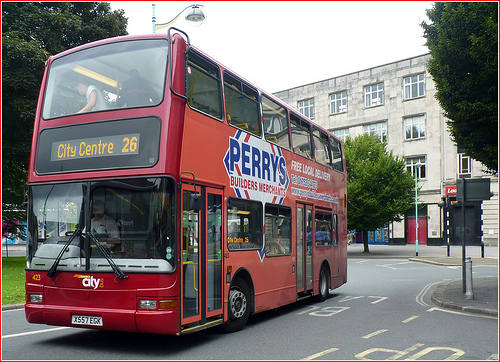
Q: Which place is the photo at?
A: It is at the road.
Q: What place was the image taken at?
A: It was taken at the road.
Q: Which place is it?
A: It is a road.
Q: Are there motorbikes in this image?
A: No, there are no motorbikes.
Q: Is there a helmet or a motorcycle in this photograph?
A: No, there are no motorcycles or helmets.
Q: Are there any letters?
A: Yes, there are letters.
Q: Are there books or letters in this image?
A: Yes, there are letters.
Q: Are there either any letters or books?
A: Yes, there are letters.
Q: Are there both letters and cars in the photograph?
A: No, there are letters but no cars.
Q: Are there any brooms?
A: No, there are no brooms.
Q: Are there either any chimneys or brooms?
A: No, there are no brooms or chimneys.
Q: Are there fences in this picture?
A: No, there are no fences.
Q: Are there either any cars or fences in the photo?
A: No, there are no fences or cars.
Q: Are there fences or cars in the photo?
A: No, there are no fences or cars.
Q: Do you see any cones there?
A: No, there are no cones.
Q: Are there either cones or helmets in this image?
A: No, there are no cones or helmets.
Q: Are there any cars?
A: No, there are no cars.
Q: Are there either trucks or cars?
A: No, there are no cars or trucks.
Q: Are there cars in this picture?
A: No, there are no cars.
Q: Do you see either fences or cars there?
A: No, there are no cars or fences.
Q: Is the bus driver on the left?
A: Yes, the driver is on the left of the image.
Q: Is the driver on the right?
A: No, the driver is on the left of the image.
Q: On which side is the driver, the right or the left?
A: The driver is on the left of the image.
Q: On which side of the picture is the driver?
A: The driver is on the left of the image.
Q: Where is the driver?
A: The driver is on the bus.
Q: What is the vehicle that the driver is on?
A: The vehicle is a bus.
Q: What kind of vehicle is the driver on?
A: The driver is on the bus.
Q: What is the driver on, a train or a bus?
A: The driver is on a bus.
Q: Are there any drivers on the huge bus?
A: Yes, there is a driver on the bus.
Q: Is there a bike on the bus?
A: No, there is a driver on the bus.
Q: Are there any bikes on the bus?
A: No, there is a driver on the bus.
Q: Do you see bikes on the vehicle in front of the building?
A: No, there is a driver on the bus.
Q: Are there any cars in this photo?
A: No, there are no cars.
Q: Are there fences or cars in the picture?
A: No, there are no cars or fences.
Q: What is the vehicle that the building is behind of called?
A: The vehicle is a bus.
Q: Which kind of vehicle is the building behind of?
A: The building is behind the bus.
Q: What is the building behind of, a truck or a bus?
A: The building is behind a bus.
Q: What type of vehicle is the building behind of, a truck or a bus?
A: The building is behind a bus.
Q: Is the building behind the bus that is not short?
A: Yes, the building is behind the bus.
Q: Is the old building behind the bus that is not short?
A: Yes, the building is behind the bus.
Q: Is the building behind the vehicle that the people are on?
A: Yes, the building is behind the bus.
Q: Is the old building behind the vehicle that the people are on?
A: Yes, the building is behind the bus.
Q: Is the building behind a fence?
A: No, the building is behind the bus.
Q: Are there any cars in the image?
A: No, there are no cars.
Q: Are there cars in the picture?
A: No, there are no cars.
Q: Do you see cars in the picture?
A: No, there are no cars.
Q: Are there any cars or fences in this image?
A: No, there are no cars or fences.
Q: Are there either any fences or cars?
A: No, there are no cars or fences.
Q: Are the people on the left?
A: Yes, the people are on the left of the image.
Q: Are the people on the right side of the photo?
A: No, the people are on the left of the image.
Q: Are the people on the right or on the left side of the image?
A: The people are on the left of the image.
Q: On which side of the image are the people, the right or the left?
A: The people are on the left of the image.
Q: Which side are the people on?
A: The people are on the left of the image.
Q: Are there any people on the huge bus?
A: Yes, there are people on the bus.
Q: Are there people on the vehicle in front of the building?
A: Yes, there are people on the bus.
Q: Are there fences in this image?
A: No, there are no fences.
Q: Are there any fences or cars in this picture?
A: No, there are no fences or cars.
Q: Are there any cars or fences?
A: No, there are no fences or cars.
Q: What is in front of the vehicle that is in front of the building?
A: The sign is in front of the bus.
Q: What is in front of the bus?
A: The sign is in front of the bus.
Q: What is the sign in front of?
A: The sign is in front of the bus.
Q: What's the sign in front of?
A: The sign is in front of the bus.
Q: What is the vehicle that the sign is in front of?
A: The vehicle is a bus.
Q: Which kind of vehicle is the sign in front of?
A: The sign is in front of the bus.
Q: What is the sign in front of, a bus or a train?
A: The sign is in front of a bus.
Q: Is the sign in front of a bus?
A: Yes, the sign is in front of a bus.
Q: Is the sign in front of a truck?
A: No, the sign is in front of a bus.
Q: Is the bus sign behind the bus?
A: No, the sign is in front of the bus.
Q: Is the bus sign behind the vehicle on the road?
A: No, the sign is in front of the bus.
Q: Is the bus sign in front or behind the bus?
A: The sign is in front of the bus.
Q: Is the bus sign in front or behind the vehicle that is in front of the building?
A: The sign is in front of the bus.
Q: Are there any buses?
A: Yes, there is a bus.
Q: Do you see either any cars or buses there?
A: Yes, there is a bus.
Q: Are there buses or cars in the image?
A: Yes, there is a bus.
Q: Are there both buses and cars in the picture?
A: No, there is a bus but no cars.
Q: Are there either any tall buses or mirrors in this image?
A: Yes, there is a tall bus.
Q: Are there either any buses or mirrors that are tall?
A: Yes, the bus is tall.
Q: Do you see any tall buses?
A: Yes, there is a tall bus.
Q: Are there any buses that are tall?
A: Yes, there is a bus that is tall.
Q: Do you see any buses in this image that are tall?
A: Yes, there is a bus that is tall.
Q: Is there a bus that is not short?
A: Yes, there is a tall bus.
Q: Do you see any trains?
A: No, there are no trains.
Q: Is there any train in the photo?
A: No, there are no trains.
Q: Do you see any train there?
A: No, there are no trains.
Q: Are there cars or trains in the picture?
A: No, there are no trains or cars.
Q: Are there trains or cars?
A: No, there are no trains or cars.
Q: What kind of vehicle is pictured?
A: The vehicle is a bus.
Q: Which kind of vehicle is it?
A: The vehicle is a bus.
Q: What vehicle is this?
A: This is a bus.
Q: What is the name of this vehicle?
A: This is a bus.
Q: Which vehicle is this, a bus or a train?
A: This is a bus.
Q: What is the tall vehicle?
A: The vehicle is a bus.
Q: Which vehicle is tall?
A: The vehicle is a bus.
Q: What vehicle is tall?
A: The vehicle is a bus.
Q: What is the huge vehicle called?
A: The vehicle is a bus.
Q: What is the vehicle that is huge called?
A: The vehicle is a bus.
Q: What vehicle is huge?
A: The vehicle is a bus.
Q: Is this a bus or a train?
A: This is a bus.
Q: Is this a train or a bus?
A: This is a bus.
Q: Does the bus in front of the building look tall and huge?
A: Yes, the bus is tall and huge.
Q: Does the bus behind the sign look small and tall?
A: No, the bus is tall but huge.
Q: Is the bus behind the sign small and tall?
A: No, the bus is tall but huge.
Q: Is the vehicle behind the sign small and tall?
A: No, the bus is tall but huge.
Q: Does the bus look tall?
A: Yes, the bus is tall.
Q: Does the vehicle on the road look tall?
A: Yes, the bus is tall.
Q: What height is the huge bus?
A: The bus is tall.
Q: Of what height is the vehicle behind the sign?
A: The bus is tall.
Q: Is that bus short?
A: No, the bus is tall.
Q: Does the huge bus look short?
A: No, the bus is tall.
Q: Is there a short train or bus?
A: No, there is a bus but it is tall.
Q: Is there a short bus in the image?
A: No, there is a bus but it is tall.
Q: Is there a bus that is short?
A: No, there is a bus but it is tall.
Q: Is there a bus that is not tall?
A: No, there is a bus but it is tall.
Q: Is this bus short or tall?
A: The bus is tall.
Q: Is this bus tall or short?
A: The bus is tall.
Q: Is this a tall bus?
A: Yes, this is a tall bus.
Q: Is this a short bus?
A: No, this is a tall bus.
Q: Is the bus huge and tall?
A: Yes, the bus is huge and tall.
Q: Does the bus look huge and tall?
A: Yes, the bus is huge and tall.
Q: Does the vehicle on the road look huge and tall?
A: Yes, the bus is huge and tall.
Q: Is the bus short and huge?
A: No, the bus is huge but tall.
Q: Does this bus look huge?
A: Yes, the bus is huge.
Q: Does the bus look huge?
A: Yes, the bus is huge.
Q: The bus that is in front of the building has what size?
A: The bus is huge.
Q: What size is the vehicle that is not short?
A: The bus is huge.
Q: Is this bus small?
A: No, the bus is huge.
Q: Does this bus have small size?
A: No, the bus is huge.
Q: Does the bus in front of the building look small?
A: No, the bus is huge.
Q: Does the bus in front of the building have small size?
A: No, the bus is huge.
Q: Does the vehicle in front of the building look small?
A: No, the bus is huge.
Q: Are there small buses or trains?
A: No, there is a bus but it is huge.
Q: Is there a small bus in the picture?
A: No, there is a bus but it is huge.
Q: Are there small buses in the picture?
A: No, there is a bus but it is huge.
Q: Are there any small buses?
A: No, there is a bus but it is huge.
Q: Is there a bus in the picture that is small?
A: No, there is a bus but it is huge.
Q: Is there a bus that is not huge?
A: No, there is a bus but it is huge.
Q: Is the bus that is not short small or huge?
A: The bus is huge.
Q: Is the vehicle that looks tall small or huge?
A: The bus is huge.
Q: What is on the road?
A: The bus is on the road.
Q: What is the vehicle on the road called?
A: The vehicle is a bus.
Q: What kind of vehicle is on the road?
A: The vehicle is a bus.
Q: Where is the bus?
A: The bus is on the road.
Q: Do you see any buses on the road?
A: Yes, there is a bus on the road.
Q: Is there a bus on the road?
A: Yes, there is a bus on the road.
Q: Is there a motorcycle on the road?
A: No, there is a bus on the road.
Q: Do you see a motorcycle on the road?
A: No, there is a bus on the road.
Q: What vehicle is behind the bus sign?
A: The vehicle is a bus.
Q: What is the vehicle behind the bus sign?
A: The vehicle is a bus.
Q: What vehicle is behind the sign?
A: The vehicle is a bus.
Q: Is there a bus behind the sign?
A: Yes, there is a bus behind the sign.